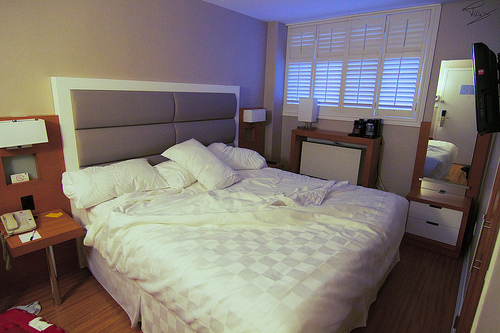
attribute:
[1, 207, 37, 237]
phone — landline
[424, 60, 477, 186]
mirror — reflective, hanging, small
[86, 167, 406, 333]
bed — messy, white, un-made, checkered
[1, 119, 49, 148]
lamp — shaded, mounted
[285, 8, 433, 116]
window — shuttered, slatted, white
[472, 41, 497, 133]
tv — mounted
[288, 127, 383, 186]
table — wooden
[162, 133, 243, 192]
pillow — white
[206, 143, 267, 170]
pillow — white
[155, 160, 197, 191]
pillow — white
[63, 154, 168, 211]
pillow — white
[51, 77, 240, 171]
headboard — grey, padded, white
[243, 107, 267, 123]
light — shaded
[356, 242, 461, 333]
floor — hardwood